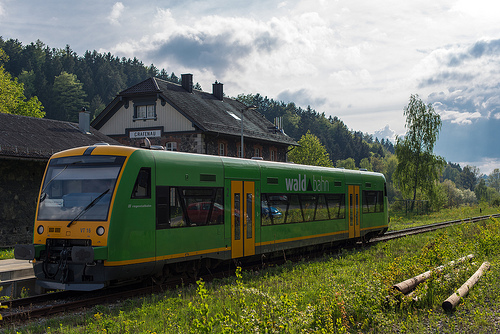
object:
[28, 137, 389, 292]
train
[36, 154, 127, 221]
windshield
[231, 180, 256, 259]
doors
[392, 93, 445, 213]
tree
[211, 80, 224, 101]
chimney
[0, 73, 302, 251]
building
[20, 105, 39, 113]
weed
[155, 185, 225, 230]
window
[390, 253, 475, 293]
pole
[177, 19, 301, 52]
cloud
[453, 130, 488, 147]
sky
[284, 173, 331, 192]
writing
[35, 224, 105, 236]
headlights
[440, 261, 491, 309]
logs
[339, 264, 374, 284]
grass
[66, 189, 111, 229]
wiper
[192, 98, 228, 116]
roof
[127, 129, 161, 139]
sign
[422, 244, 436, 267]
plants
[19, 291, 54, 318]
railroad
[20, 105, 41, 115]
wildflowers